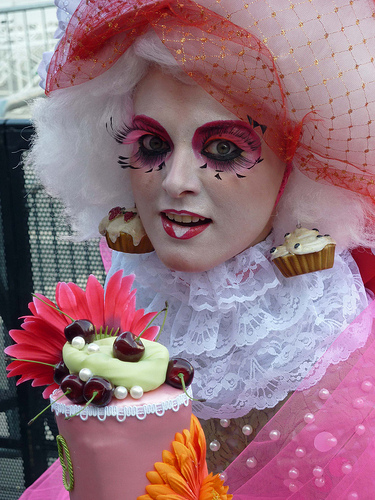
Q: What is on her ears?
A: Cupcakes.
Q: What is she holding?
A: Sweets.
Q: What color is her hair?
A: White.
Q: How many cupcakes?
A: 2.